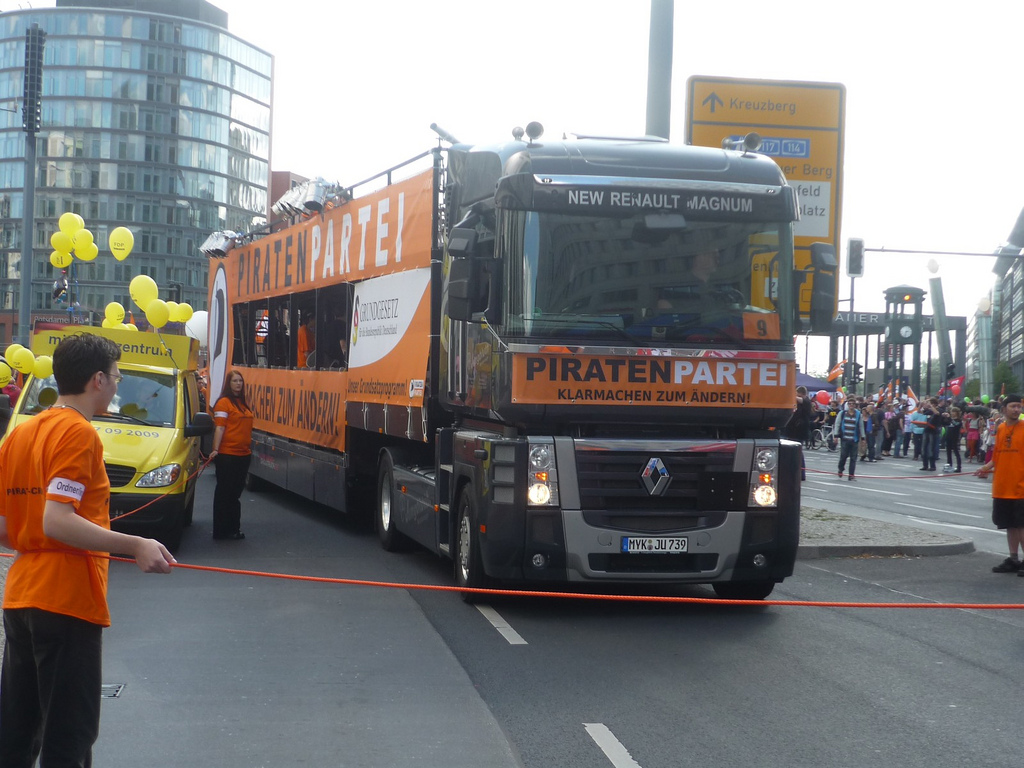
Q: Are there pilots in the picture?
A: No, there are no pilots.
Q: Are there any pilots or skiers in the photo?
A: No, there are no pilots or skiers.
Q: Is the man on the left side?
A: Yes, the man is on the left of the image.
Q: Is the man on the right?
A: No, the man is on the left of the image.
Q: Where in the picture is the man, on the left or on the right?
A: The man is on the left of the image.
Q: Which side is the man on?
A: The man is on the left of the image.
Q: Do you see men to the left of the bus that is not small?
A: Yes, there is a man to the left of the bus.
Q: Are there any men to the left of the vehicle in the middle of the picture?
A: Yes, there is a man to the left of the bus.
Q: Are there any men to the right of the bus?
A: No, the man is to the left of the bus.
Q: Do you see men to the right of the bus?
A: No, the man is to the left of the bus.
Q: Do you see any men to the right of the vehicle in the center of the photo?
A: No, the man is to the left of the bus.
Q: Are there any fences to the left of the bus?
A: No, there is a man to the left of the bus.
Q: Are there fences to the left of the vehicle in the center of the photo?
A: No, there is a man to the left of the bus.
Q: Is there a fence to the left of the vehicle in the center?
A: No, there is a man to the left of the bus.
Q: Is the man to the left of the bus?
A: Yes, the man is to the left of the bus.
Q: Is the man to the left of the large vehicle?
A: Yes, the man is to the left of the bus.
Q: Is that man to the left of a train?
A: No, the man is to the left of the bus.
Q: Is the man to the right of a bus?
A: No, the man is to the left of a bus.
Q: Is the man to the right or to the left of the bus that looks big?
A: The man is to the left of the bus.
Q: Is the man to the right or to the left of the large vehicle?
A: The man is to the left of the bus.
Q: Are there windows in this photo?
A: Yes, there is a window.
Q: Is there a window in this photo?
A: Yes, there is a window.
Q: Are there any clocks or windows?
A: Yes, there is a window.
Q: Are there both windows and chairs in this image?
A: No, there is a window but no chairs.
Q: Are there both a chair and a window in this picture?
A: No, there is a window but no chairs.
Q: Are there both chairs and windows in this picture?
A: No, there is a window but no chairs.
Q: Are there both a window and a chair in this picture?
A: No, there is a window but no chairs.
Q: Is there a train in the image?
A: No, there are no trains.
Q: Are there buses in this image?
A: Yes, there is a bus.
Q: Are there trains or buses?
A: Yes, there is a bus.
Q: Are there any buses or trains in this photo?
A: Yes, there is a bus.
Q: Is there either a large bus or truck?
A: Yes, there is a large bus.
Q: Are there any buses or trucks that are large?
A: Yes, the bus is large.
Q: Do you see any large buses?
A: Yes, there is a large bus.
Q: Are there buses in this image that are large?
A: Yes, there is a bus that is large.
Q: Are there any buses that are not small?
A: Yes, there is a large bus.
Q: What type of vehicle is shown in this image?
A: The vehicle is a bus.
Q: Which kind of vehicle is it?
A: The vehicle is a bus.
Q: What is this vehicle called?
A: This is a bus.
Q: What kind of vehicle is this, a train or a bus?
A: This is a bus.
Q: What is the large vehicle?
A: The vehicle is a bus.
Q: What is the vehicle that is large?
A: The vehicle is a bus.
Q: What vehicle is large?
A: The vehicle is a bus.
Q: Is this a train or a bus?
A: This is a bus.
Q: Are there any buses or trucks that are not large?
A: No, there is a bus but it is large.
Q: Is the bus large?
A: Yes, the bus is large.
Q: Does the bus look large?
A: Yes, the bus is large.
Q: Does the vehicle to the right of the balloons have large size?
A: Yes, the bus is large.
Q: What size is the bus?
A: The bus is large.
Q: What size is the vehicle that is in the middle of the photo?
A: The bus is large.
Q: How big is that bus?
A: The bus is large.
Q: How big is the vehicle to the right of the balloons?
A: The bus is large.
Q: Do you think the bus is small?
A: No, the bus is large.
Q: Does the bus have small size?
A: No, the bus is large.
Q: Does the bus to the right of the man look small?
A: No, the bus is large.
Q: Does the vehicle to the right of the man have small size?
A: No, the bus is large.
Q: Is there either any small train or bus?
A: No, there is a bus but it is large.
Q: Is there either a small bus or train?
A: No, there is a bus but it is large.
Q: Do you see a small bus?
A: No, there is a bus but it is large.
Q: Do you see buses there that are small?
A: No, there is a bus but it is large.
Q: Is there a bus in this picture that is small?
A: No, there is a bus but it is large.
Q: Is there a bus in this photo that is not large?
A: No, there is a bus but it is large.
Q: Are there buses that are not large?
A: No, there is a bus but it is large.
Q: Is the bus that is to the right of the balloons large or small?
A: The bus is large.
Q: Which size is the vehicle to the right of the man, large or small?
A: The bus is large.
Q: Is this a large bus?
A: Yes, this is a large bus.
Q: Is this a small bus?
A: No, this is a large bus.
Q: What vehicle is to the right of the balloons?
A: The vehicle is a bus.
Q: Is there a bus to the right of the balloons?
A: Yes, there is a bus to the right of the balloons.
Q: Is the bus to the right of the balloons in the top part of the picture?
A: Yes, the bus is to the right of the balloons.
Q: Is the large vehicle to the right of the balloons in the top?
A: Yes, the bus is to the right of the balloons.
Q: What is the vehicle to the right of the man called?
A: The vehicle is a bus.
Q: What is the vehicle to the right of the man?
A: The vehicle is a bus.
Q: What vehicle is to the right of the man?
A: The vehicle is a bus.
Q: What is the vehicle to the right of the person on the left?
A: The vehicle is a bus.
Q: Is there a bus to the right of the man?
A: Yes, there is a bus to the right of the man.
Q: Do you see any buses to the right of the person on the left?
A: Yes, there is a bus to the right of the man.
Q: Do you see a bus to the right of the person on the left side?
A: Yes, there is a bus to the right of the man.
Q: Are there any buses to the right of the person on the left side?
A: Yes, there is a bus to the right of the man.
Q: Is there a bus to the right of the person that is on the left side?
A: Yes, there is a bus to the right of the man.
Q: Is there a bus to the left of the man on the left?
A: No, the bus is to the right of the man.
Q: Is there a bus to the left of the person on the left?
A: No, the bus is to the right of the man.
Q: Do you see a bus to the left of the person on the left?
A: No, the bus is to the right of the man.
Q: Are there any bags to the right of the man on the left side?
A: No, there is a bus to the right of the man.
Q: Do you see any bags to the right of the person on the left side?
A: No, there is a bus to the right of the man.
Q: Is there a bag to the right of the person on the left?
A: No, there is a bus to the right of the man.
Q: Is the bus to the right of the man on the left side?
A: Yes, the bus is to the right of the man.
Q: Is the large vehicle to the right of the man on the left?
A: Yes, the bus is to the right of the man.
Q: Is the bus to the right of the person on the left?
A: Yes, the bus is to the right of the man.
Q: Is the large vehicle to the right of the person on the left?
A: Yes, the bus is to the right of the man.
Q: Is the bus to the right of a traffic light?
A: No, the bus is to the right of the man.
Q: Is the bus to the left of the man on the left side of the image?
A: No, the bus is to the right of the man.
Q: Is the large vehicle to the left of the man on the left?
A: No, the bus is to the right of the man.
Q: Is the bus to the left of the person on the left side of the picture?
A: No, the bus is to the right of the man.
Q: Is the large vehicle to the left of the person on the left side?
A: No, the bus is to the right of the man.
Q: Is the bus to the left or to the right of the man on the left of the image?
A: The bus is to the right of the man.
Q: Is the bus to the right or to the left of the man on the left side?
A: The bus is to the right of the man.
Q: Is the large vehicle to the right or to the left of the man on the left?
A: The bus is to the right of the man.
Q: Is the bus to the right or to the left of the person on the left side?
A: The bus is to the right of the man.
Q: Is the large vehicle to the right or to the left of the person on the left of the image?
A: The bus is to the right of the man.